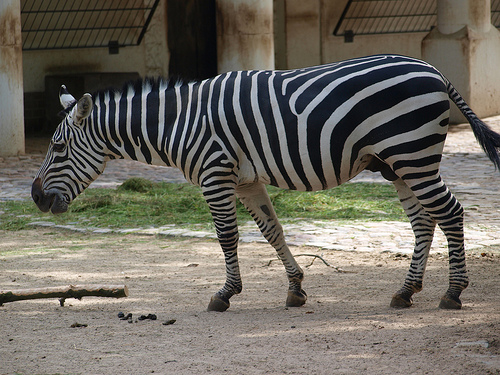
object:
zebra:
[32, 54, 499, 315]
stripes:
[173, 83, 287, 149]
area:
[2, 52, 500, 375]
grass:
[88, 197, 199, 224]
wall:
[0, 0, 496, 116]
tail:
[442, 75, 500, 176]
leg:
[198, 163, 242, 307]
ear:
[71, 92, 93, 125]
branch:
[0, 285, 130, 307]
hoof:
[205, 295, 230, 313]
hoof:
[284, 294, 307, 306]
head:
[30, 84, 107, 214]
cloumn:
[215, 0, 275, 73]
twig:
[265, 251, 357, 274]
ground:
[1, 159, 499, 368]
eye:
[52, 143, 65, 152]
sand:
[218, 334, 430, 368]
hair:
[71, 76, 196, 103]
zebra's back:
[59, 52, 418, 104]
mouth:
[30, 176, 66, 215]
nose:
[31, 190, 44, 206]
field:
[1, 95, 500, 242]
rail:
[6, 0, 157, 52]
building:
[2, 0, 498, 155]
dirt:
[0, 230, 500, 375]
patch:
[90, 179, 207, 225]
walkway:
[1, 152, 185, 203]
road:
[6, 221, 500, 335]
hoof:
[388, 292, 413, 308]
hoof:
[438, 296, 465, 309]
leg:
[235, 184, 309, 302]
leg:
[393, 169, 436, 303]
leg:
[392, 155, 469, 304]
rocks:
[160, 318, 176, 328]